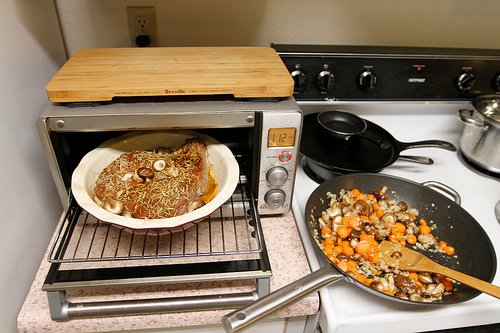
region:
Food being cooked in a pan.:
[297, 173, 487, 313]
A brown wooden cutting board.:
[47, 43, 294, 98]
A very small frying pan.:
[319, 109, 390, 149]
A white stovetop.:
[300, 109, 497, 329]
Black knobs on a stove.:
[288, 63, 498, 91]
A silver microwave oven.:
[34, 103, 303, 308]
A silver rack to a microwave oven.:
[47, 198, 267, 263]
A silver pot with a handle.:
[453, 98, 498, 173]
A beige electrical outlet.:
[123, 6, 161, 48]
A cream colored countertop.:
[12, 207, 322, 331]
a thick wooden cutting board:
[49, 47, 296, 102]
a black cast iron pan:
[307, 109, 457, 177]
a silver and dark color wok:
[226, 170, 499, 326]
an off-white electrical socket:
[126, 5, 158, 45]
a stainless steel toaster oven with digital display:
[39, 98, 301, 320]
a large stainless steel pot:
[450, 90, 497, 175]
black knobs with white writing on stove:
[290, 63, 475, 98]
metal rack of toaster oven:
[50, 186, 264, 263]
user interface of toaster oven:
[262, 124, 297, 210]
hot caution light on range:
[410, 59, 429, 74]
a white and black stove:
[280, 39, 497, 330]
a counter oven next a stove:
[34, 32, 302, 310]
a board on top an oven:
[34, 23, 305, 214]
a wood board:
[43, 35, 298, 105]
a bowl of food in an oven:
[56, 126, 248, 234]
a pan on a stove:
[219, 165, 496, 331]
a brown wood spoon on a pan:
[377, 239, 498, 310]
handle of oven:
[43, 288, 277, 324]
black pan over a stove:
[299, 108, 461, 175]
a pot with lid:
[451, 89, 496, 177]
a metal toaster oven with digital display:
[37, 98, 304, 318]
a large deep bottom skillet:
[239, 167, 499, 331]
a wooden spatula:
[375, 238, 499, 298]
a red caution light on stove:
[412, 62, 425, 73]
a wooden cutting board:
[44, 48, 294, 101]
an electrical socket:
[124, 8, 158, 45]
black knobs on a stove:
[287, 69, 476, 92]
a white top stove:
[292, 115, 499, 330]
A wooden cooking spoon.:
[369, 239, 497, 302]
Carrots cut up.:
[317, 182, 456, 315]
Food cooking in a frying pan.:
[297, 166, 498, 316]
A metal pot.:
[449, 94, 499, 179]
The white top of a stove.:
[294, 107, 498, 332]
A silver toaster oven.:
[37, 104, 304, 331]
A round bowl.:
[69, 132, 239, 241]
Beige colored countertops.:
[18, 215, 322, 330]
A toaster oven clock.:
[267, 127, 294, 148]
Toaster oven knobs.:
[265, 167, 286, 209]